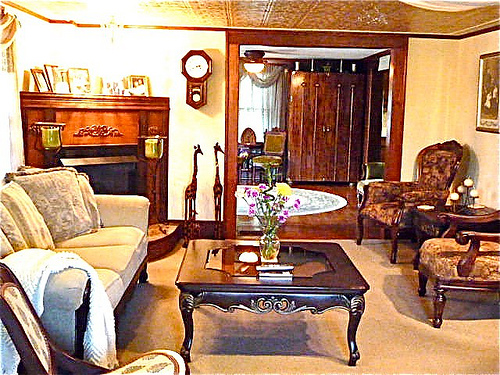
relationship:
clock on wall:
[161, 55, 228, 110] [2, 3, 227, 238]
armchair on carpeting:
[416, 210, 499, 328] [114, 238, 498, 373]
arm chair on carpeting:
[356, 140, 468, 264] [114, 238, 498, 373]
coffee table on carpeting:
[174, 238, 369, 366] [114, 238, 498, 373]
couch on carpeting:
[0, 166, 151, 361] [114, 238, 498, 373]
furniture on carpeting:
[1, 263, 191, 374] [114, 238, 498, 373]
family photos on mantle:
[25, 56, 161, 99] [20, 89, 170, 117]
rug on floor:
[232, 177, 351, 224] [135, 214, 483, 374]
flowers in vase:
[232, 176, 299, 228] [253, 224, 280, 261]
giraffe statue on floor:
[213, 142, 226, 225] [41, 230, 496, 372]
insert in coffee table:
[203, 245, 335, 278] [174, 238, 369, 366]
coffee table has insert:
[174, 238, 369, 366] [203, 245, 335, 278]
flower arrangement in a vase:
[240, 181, 301, 236] [249, 216, 291, 261]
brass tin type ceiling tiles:
[228, 51, 366, 111] [243, 7, 405, 34]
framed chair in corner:
[391, 162, 441, 256] [372, 114, 451, 243]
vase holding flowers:
[262, 224, 337, 261] [262, 163, 360, 231]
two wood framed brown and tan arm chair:
[322, 156, 422, 245] [357, 137, 469, 261]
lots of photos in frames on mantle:
[31, 64, 154, 102] [42, 99, 204, 199]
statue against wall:
[213, 142, 226, 235] [165, 94, 224, 194]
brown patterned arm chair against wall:
[348, 154, 397, 214] [404, 33, 499, 208]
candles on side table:
[232, 220, 254, 300] [404, 163, 476, 297]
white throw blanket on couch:
[73, 264, 123, 375] [7, 154, 164, 352]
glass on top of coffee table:
[206, 241, 336, 281] [177, 232, 366, 368]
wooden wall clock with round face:
[182, 64, 234, 164] [182, 51, 208, 81]